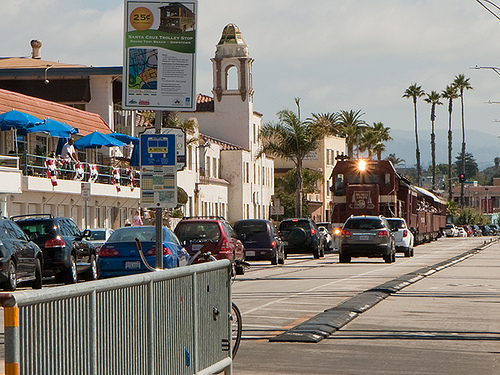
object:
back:
[342, 228, 387, 246]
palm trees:
[400, 81, 426, 185]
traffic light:
[453, 154, 469, 183]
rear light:
[44, 234, 66, 248]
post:
[150, 202, 170, 269]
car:
[338, 213, 396, 263]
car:
[278, 218, 327, 259]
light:
[378, 230, 389, 237]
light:
[343, 230, 351, 238]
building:
[447, 179, 497, 225]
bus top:
[139, 132, 177, 209]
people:
[56, 139, 79, 179]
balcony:
[81, 161, 141, 199]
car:
[173, 216, 246, 277]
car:
[233, 218, 285, 265]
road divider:
[268, 239, 498, 341]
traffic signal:
[457, 169, 466, 184]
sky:
[1, 1, 497, 170]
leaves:
[401, 82, 425, 100]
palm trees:
[422, 88, 444, 190]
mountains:
[394, 128, 498, 170]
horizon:
[385, 168, 497, 172]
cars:
[0, 215, 47, 293]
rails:
[1, 256, 233, 373]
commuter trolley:
[326, 157, 452, 252]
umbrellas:
[72, 129, 127, 152]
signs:
[139, 134, 178, 210]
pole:
[155, 103, 162, 270]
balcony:
[24, 150, 82, 194]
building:
[0, 87, 142, 232]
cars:
[277, 204, 345, 277]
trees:
[450, 71, 473, 204]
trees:
[439, 82, 460, 196]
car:
[325, 154, 448, 248]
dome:
[211, 20, 262, 93]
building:
[195, 17, 276, 223]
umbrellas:
[0, 106, 45, 129]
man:
[59, 137, 77, 177]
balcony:
[0, 154, 23, 194]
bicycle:
[133, 236, 252, 362]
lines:
[241, 236, 478, 342]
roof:
[4, 86, 117, 146]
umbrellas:
[23, 114, 80, 140]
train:
[325, 145, 466, 259]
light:
[349, 152, 379, 180]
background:
[306, 94, 497, 250]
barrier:
[1, 258, 237, 375]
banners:
[42, 158, 59, 187]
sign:
[80, 182, 91, 198]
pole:
[80, 180, 92, 236]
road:
[202, 198, 499, 373]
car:
[96, 225, 191, 280]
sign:
[121, 0, 199, 111]